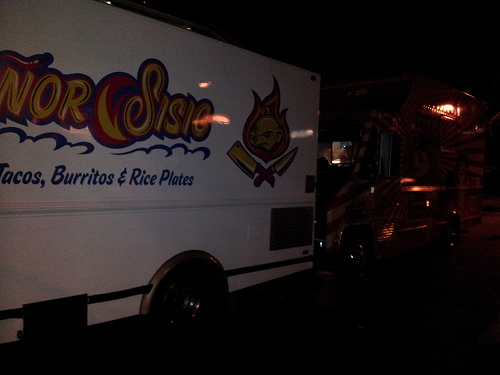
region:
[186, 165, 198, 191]
Blue letter on a white bus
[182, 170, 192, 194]
Blue letter on a white bus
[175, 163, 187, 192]
Blue letter on a white bus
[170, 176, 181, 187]
Blue letter on a white bus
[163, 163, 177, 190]
Blue letter on a white bus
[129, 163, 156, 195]
Blue letter on a white bus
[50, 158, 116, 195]
Blue letter on a white bus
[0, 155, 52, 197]
Blue letter on a white bus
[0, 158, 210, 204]
Blue letter on a white bus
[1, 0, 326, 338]
white trailer parked on street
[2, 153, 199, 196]
blue lettering on white background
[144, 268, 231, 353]
wheel on the trailer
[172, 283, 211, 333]
rim of the wheel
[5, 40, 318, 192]
business logo on side of trailer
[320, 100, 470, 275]
food truck parked on street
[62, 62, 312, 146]
reflections on the white trialer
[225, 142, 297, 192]
knives in the business logo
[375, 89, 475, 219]
light reflections on food truck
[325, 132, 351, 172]
front windshield of food truck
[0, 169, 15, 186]
The letter is blue.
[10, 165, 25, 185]
The letter is blue.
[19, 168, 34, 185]
The letter is blue.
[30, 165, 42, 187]
The letter is blue.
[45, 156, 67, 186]
The letter is blue.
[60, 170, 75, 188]
The letter is blue.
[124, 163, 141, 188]
The letter is blue.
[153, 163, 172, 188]
The letter is blue.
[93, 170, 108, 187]
The letter is blue.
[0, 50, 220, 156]
red and yellow writing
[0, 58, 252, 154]
writing on side of truck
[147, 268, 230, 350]
black wheel on truck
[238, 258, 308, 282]
black stripe on bottom of truck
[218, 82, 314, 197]
image on side of truck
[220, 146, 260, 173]
picture of meat cleaver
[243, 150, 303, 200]
image of kitchen knife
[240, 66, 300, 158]
red and yellow flames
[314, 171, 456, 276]
cars parked behind truck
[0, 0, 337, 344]
large white truck parked